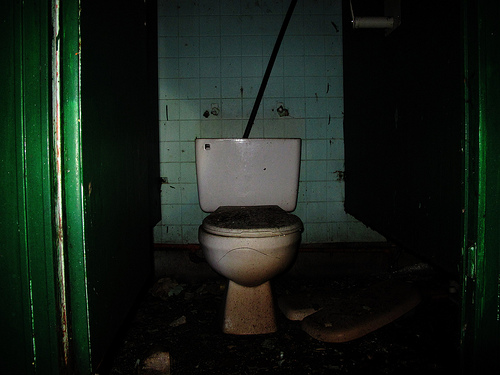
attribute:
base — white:
[224, 280, 275, 337]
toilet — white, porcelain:
[197, 133, 303, 336]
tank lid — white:
[195, 136, 301, 216]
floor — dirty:
[107, 265, 496, 372]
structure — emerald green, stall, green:
[337, 0, 471, 282]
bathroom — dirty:
[0, 0, 497, 372]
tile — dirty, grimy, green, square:
[198, 95, 224, 122]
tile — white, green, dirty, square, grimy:
[219, 97, 244, 120]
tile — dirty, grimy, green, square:
[241, 95, 264, 118]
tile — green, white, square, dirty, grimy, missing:
[267, 97, 289, 120]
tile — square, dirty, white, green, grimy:
[242, 118, 265, 136]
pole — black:
[243, 2, 298, 142]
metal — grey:
[52, 1, 72, 370]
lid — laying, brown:
[302, 272, 420, 345]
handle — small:
[341, 0, 402, 37]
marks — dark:
[328, 166, 346, 182]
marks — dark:
[196, 103, 222, 124]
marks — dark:
[273, 101, 294, 124]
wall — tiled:
[151, 2, 386, 244]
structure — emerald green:
[0, 1, 162, 367]